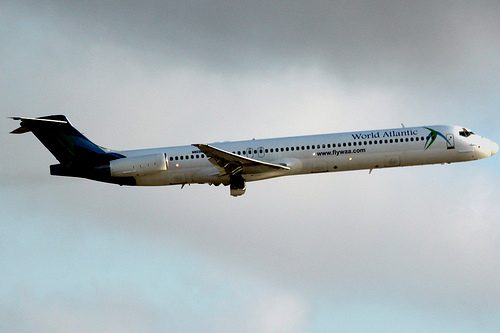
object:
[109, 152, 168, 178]
engine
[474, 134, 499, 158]
nose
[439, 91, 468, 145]
sun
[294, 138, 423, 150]
windows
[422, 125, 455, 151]
design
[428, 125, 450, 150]
logo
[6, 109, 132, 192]
tail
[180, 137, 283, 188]
wing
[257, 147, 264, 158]
emergency doors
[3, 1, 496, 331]
sky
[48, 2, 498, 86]
dark cloud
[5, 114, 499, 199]
airplane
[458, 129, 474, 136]
windshield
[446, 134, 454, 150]
door